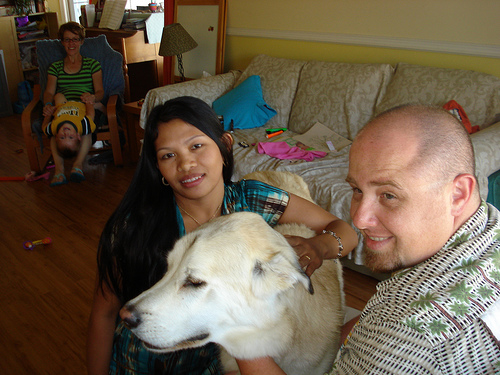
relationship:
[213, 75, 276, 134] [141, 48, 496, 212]
pillow on sofa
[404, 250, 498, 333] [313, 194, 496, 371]
palm trees on shirt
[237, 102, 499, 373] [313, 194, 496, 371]
man wearing shirt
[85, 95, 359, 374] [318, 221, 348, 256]
woman wearing bracelet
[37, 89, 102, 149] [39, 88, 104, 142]
child wearing shirt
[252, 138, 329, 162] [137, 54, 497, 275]
pink cloth on sofa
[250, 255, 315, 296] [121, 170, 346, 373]
ears on dog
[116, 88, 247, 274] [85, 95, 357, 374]
hair on woman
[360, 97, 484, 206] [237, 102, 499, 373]
hair on man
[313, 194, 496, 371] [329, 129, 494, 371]
shirt on man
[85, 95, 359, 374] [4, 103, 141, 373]
woman sitting on floor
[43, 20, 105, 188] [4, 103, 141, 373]
woman sitting on floor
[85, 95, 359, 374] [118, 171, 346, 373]
woman sitting around lab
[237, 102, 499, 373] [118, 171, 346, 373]
man sitting around lab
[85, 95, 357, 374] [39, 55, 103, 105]
woman wearing shirt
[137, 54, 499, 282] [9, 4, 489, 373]
sofa in living room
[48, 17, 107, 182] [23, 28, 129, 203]
woman sitting on rocking chair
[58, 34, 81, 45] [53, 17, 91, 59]
glasses on woman's face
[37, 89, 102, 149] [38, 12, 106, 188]
child on woman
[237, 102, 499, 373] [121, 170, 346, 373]
man with dog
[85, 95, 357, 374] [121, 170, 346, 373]
woman with dog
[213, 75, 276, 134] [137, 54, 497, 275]
pillow on sofa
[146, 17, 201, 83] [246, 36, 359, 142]
lamp to left of sofa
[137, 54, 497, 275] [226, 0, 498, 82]
sofa against wall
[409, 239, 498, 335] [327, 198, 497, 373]
palm trees on shirt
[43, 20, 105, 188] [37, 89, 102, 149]
woman sitting with child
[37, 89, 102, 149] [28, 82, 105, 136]
child in lap